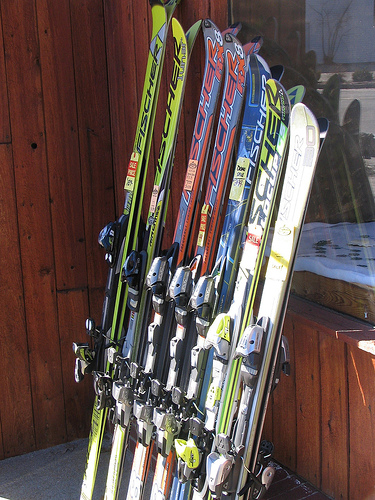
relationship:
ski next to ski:
[179, 51, 289, 498] [214, 78, 331, 499]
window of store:
[236, 0, 375, 327] [0, 0, 371, 496]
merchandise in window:
[199, 101, 321, 499] [236, 0, 375, 327]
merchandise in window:
[194, 77, 295, 499] [236, 0, 375, 327]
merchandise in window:
[170, 50, 268, 498] [236, 0, 375, 327]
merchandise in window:
[119, 23, 226, 499] [236, 0, 375, 327]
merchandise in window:
[102, 17, 194, 499] [236, 0, 375, 327]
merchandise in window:
[75, 2, 174, 499] [236, 0, 375, 327]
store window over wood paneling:
[219, 1, 372, 129] [286, 294, 371, 351]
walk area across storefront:
[305, 221, 374, 278] [2, 1, 373, 498]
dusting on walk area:
[2, 429, 180, 498] [305, 221, 374, 278]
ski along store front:
[70, 1, 168, 498] [116, 1, 373, 498]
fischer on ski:
[135, 43, 162, 158] [82, 5, 168, 499]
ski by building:
[170, 54, 294, 498] [0, 2, 373, 498]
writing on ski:
[142, 63, 152, 156] [132, 84, 158, 138]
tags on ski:
[120, 148, 256, 255] [101, 16, 190, 499]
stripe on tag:
[246, 230, 262, 246] [122, 151, 139, 191]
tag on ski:
[124, 151, 140, 191] [70, 1, 168, 498]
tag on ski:
[146, 182, 159, 215] [100, 16, 188, 498]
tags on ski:
[124, 151, 263, 272] [126, 18, 224, 499]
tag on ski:
[196, 204, 209, 248] [149, 32, 247, 499]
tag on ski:
[229, 156, 250, 202] [170, 54, 271, 498]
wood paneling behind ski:
[261, 291, 375, 500] [126, 18, 224, 499]